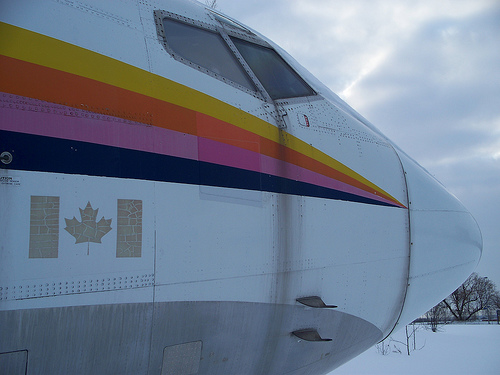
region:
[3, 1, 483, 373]
large plane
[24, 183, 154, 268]
faded Canadian flag on the side of the plane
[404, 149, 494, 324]
nose of the plane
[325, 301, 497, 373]
white snow on the ground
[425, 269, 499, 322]
tree with no leaves on it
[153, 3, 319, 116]
window on the front of the plane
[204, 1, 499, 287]
thick clouds in the sky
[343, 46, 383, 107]
light shining through the clouds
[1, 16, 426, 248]
stripes on the side of the plane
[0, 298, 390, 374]
bottom of the plane is gray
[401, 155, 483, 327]
nose of white airplane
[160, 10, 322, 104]
windows of plane's cockpit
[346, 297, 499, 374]
snow covered ground behind airplane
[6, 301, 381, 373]
gray underside of the airplane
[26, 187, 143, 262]
canadian flag sticker on the airplane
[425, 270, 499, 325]
tree in the far distance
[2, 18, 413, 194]
yellow stripe on airplane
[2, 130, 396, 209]
navy stripe on airplane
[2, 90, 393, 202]
pink stripe on airplane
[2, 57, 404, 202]
orange stripe on airplane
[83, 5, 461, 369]
A big plane's head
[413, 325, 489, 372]
A white snow ground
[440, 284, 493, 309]
A short green tree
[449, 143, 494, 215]
A white cloud sky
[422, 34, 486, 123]
A white cloud sky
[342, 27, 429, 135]
A white cloud sky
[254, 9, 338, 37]
A white cloud sky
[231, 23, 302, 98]
A glass train window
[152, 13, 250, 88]
A glass train window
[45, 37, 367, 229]
A coloured plane's body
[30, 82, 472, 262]
FRONT OF AIRLINER AIRCRAFT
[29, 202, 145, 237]
CANADIAN FLAG ON PLANE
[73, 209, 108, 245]
MAPLE LEAF ON PLANE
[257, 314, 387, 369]
GRAY UNDER BELLY OF PLANE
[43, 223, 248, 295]
WHITE FUSELAGE OF PLANE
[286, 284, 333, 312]
SMALL SENSOR ON PLANE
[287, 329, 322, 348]
SMALL SENSOR ON PLANE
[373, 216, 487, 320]
WHITE NOSE OF PLANE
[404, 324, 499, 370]
WHITE SNOW ON GROUND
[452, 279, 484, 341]
TREE GROWING IN DISTANCE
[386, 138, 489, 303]
A plane's sharp end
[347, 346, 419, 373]
A white snow ground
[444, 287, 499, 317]
A leafless small tree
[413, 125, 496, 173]
A white cloud sky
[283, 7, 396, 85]
A white cloud sky